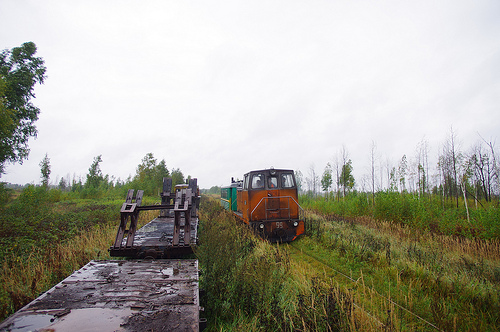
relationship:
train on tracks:
[218, 164, 309, 250] [276, 240, 437, 331]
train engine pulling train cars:
[239, 172, 304, 241] [218, 179, 238, 212]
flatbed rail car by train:
[0, 173, 205, 329] [218, 164, 309, 250]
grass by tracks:
[200, 192, 500, 332] [276, 240, 437, 331]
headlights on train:
[256, 218, 299, 230] [218, 164, 309, 250]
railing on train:
[250, 195, 305, 219] [218, 164, 309, 250]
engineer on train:
[253, 175, 288, 188] [218, 164, 309, 250]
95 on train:
[273, 221, 288, 231] [218, 164, 309, 250]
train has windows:
[218, 164, 309, 250] [240, 174, 249, 188]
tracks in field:
[276, 240, 437, 331] [0, 177, 499, 332]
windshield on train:
[249, 172, 296, 189] [218, 164, 309, 250]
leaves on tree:
[2, 44, 46, 169] [2, 41, 39, 181]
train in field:
[218, 164, 309, 250] [0, 177, 499, 332]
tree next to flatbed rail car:
[2, 41, 39, 181] [0, 173, 205, 329]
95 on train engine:
[273, 221, 288, 231] [239, 172, 304, 241]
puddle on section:
[38, 306, 122, 330] [0, 258, 205, 329]